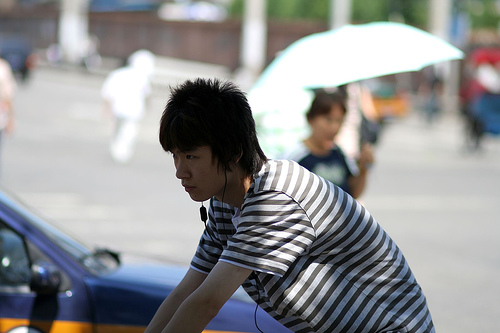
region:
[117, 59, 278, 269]
Teenager listening to headphones.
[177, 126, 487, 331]
Gray and dark gay shirt.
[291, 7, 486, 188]
Person holding an umbrella.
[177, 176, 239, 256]
Volume control for head phones.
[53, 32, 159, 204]
Blurry person in back ground.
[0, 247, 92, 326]
Side mirror on a car.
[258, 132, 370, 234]
Blue and white t- shirt.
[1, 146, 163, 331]
Blue and yellow car.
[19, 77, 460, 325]
Teenager with spiky hair.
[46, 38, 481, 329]
Two people in a photo.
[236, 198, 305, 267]
The right sleeve of the striped shirt.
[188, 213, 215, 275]
The left sleeve of the striped shirt.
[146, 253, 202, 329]
The guy's left arm.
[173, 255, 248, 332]
The guy's right arm.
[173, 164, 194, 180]
The nose of the guy.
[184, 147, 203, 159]
The guy's right eye.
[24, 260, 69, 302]
The side view mirror on the blue car.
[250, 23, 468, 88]
The white umbrella that the woman is holding.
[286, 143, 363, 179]
The blue and white shirt the woman is wearing.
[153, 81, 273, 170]
The guy's black hair.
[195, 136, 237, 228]
head phones in man's ear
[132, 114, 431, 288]
shadow on man's tee shirt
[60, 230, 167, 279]
windshield wiper on car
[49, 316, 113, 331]
orange line at side of car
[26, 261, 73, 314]
black car side mirror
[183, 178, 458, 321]
black and white tee shirt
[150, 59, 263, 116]
spikes on man's head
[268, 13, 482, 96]
white open umbrella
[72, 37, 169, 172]
person in white suit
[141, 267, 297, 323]
man's bare arms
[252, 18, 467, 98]
the umbrella is white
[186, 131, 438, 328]
the shirt is black and white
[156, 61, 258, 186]
the hair is black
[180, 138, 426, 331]
the shirt is stripped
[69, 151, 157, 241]
the street is gray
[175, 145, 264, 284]
the boy has headphones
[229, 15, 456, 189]
the person is holding an umbrella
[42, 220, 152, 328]
the car is purple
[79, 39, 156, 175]
the man is walking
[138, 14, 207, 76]
the fence is brown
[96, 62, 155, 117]
the shirt is white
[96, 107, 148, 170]
the pants are white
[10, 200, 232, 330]
the car is purple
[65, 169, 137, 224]
the street is gray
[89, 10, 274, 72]
the fence is brown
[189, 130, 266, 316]
the headphones are black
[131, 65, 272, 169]
the hair is short